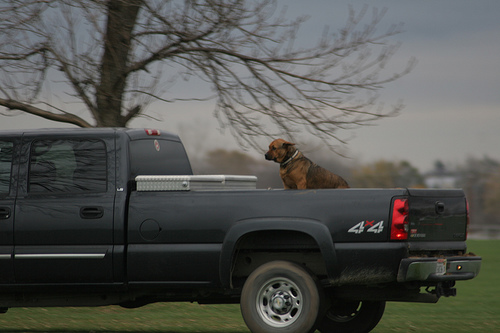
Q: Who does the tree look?
A: Bare.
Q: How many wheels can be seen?
A: Two.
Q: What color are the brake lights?
A: Red.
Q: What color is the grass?
A: Green.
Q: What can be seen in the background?
A: Trees.